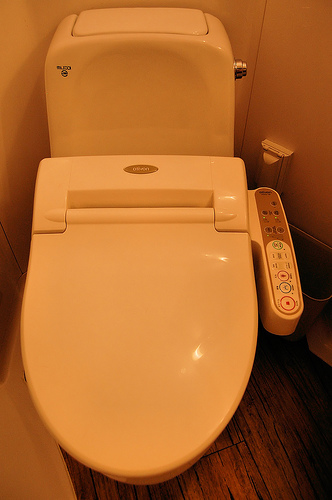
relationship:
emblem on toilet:
[125, 162, 157, 173] [21, 6, 302, 484]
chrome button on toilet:
[234, 59, 246, 77] [21, 6, 302, 484]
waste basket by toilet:
[287, 222, 330, 340] [21, 6, 302, 484]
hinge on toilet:
[68, 202, 215, 229] [21, 30, 267, 453]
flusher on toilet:
[232, 56, 247, 79] [21, 6, 302, 484]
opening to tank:
[69, 5, 209, 36] [42, 5, 237, 159]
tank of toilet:
[42, 5, 237, 159] [18, 6, 258, 486]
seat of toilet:
[16, 149, 259, 490] [21, 6, 302, 484]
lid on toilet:
[20, 187, 274, 490] [26, 150, 275, 484]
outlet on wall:
[260, 136, 293, 200] [207, 0, 329, 255]